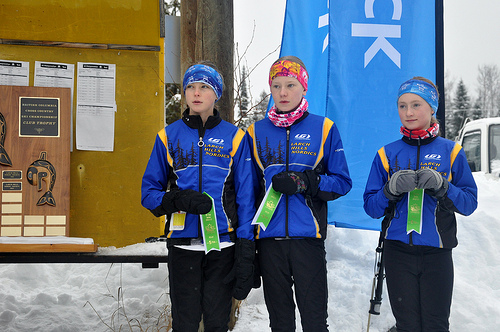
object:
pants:
[382, 238, 454, 332]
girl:
[362, 76, 477, 332]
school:
[0, 0, 171, 270]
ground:
[292, 136, 319, 202]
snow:
[9, 270, 152, 328]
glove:
[416, 168, 444, 190]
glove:
[388, 170, 418, 196]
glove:
[271, 170, 310, 195]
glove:
[158, 189, 213, 215]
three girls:
[139, 56, 476, 332]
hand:
[416, 168, 444, 190]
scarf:
[268, 97, 309, 127]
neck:
[275, 109, 301, 120]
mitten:
[166, 193, 201, 207]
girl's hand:
[161, 189, 210, 214]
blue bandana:
[397, 80, 439, 116]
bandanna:
[268, 60, 308, 91]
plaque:
[2, 196, 23, 237]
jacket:
[362, 137, 479, 251]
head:
[183, 62, 224, 113]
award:
[200, 191, 221, 255]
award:
[251, 182, 284, 231]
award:
[406, 186, 425, 235]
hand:
[167, 189, 212, 214]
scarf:
[399, 121, 439, 139]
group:
[138, 50, 478, 328]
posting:
[0, 58, 31, 88]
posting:
[31, 53, 78, 156]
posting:
[74, 54, 118, 155]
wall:
[0, 39, 168, 250]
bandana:
[183, 64, 223, 103]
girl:
[139, 60, 256, 332]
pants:
[258, 236, 329, 332]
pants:
[165, 246, 235, 331]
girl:
[235, 55, 351, 332]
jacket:
[239, 111, 352, 240]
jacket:
[139, 109, 256, 247]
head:
[271, 56, 308, 112]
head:
[397, 77, 439, 131]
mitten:
[237, 255, 255, 281]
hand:
[229, 255, 260, 300]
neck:
[407, 122, 430, 139]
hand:
[272, 170, 315, 195]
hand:
[387, 170, 418, 196]